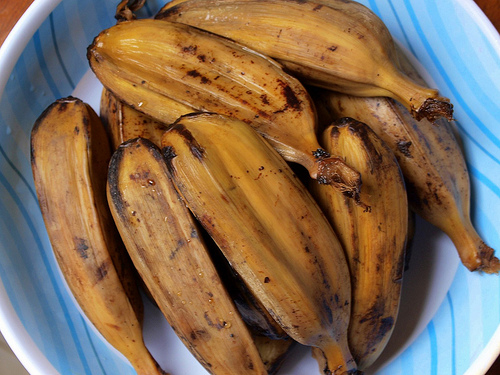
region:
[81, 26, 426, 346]
these are the bananas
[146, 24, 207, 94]
the banana is boiled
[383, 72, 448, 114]
this is the stalk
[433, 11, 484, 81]
this is a plate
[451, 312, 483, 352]
the plate is made of plastic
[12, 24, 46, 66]
the plate is blue and white in color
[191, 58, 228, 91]
the banana has patches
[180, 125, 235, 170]
this is the pearl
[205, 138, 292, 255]
the banana is not pearled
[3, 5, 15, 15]
this is a table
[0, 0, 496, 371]
A blue and white bowl holding plantains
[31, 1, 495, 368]
A pile of plantains in a bowl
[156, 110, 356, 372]
A wide plantain on top of the others, in the middle of the bowl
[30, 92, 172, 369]
A corndog-shaped plantain on the left side of the bowl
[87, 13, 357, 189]
A wide plantain close to the top, with many shiny black spots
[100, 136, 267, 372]
A plantain beside the wide middle one with blacked corners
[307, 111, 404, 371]
A thick plantain behind two others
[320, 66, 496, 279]
A very visible plantain at the bottom of the bowl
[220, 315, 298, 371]
A barely visible plantain at the very bottom of the bowl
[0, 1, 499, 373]
A bowl of plantains on a reddish wooden counter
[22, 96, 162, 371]
a cooked banana in a bowl.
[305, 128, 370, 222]
the top most part of a banana.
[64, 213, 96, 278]
a brown spot on a banana.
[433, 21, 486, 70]
a section of a blue bowl.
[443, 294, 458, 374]
a blue line in a bowl.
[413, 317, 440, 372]
a section of dark blue paint.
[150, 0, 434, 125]
a banana in a bowl.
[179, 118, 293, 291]
a banana peel on a banana.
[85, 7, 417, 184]
a cooked banana.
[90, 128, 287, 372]
a slimey banana.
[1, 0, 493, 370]
plantains in a blue bowl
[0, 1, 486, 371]
blue bowl with fruit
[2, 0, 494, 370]
ripe plantains in a bowl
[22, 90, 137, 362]
one plantain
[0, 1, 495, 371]
very ripe fruit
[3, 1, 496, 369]
tropical fruit in a bowl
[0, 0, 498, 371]
short, brown, ripe bananas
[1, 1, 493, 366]
fruit in focus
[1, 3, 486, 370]
blue bowl with ripe plantains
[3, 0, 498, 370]
pile of ripe plantains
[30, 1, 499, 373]
Fruit is in a bowl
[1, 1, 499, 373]
The bowl is white with a blue striped design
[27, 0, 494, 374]
The fruit is golden brown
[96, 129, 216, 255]
Long dark black spots are on the fruit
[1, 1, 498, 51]
Above the bowl the table can be seen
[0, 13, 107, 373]
Two green stripes are on the left side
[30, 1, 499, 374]
Nine pieces of fruit are shown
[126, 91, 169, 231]
Two water drops can be seen on the fruit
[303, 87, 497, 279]
The stems are decaying faster than the rest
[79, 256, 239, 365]
The bottom left two show bruising